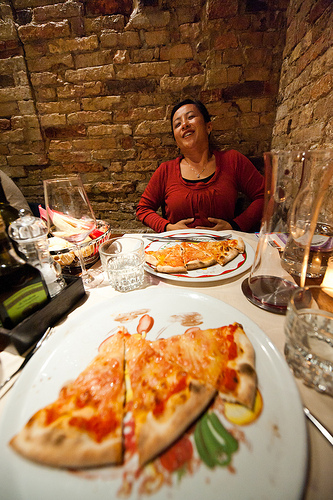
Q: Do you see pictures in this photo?
A: No, there are no pictures.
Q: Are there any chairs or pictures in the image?
A: No, there are no pictures or chairs.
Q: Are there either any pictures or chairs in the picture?
A: No, there are no pictures or chairs.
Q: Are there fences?
A: No, there are no fences.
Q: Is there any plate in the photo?
A: Yes, there is a plate.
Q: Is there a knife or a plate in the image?
A: Yes, there is a plate.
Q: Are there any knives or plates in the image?
A: Yes, there is a plate.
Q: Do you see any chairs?
A: No, there are no chairs.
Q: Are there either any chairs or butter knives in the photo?
A: No, there are no chairs or butter knives.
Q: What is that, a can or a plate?
A: That is a plate.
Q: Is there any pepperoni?
A: Yes, there is pepperoni.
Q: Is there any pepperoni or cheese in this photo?
A: Yes, there is pepperoni.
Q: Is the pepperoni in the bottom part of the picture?
A: Yes, the pepperoni is in the bottom of the image.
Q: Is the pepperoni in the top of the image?
A: No, the pepperoni is in the bottom of the image.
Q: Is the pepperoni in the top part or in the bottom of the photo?
A: The pepperoni is in the bottom of the image.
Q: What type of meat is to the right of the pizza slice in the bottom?
A: The meat is pepperoni.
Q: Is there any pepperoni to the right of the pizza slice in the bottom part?
A: Yes, there is pepperoni to the right of the pizza slice.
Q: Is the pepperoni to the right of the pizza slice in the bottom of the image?
A: Yes, the pepperoni is to the right of the pizza slice.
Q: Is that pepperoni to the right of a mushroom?
A: No, the pepperoni is to the right of the pizza slice.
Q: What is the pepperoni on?
A: The pepperoni is on the plate.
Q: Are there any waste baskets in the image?
A: No, there are no waste baskets.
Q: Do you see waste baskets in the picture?
A: No, there are no waste baskets.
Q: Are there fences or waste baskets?
A: No, there are no waste baskets or fences.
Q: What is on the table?
A: The basket is on the table.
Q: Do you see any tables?
A: Yes, there is a table.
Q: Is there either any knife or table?
A: Yes, there is a table.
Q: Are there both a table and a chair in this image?
A: No, there is a table but no chairs.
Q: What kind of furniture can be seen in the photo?
A: The furniture is a table.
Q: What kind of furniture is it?
A: The piece of furniture is a table.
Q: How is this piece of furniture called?
A: That is a table.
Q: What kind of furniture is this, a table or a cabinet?
A: That is a table.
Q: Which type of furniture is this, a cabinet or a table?
A: That is a table.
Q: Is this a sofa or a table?
A: This is a table.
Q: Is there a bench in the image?
A: No, there are no benches.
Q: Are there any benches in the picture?
A: No, there are no benches.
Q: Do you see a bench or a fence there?
A: No, there are no benches or fences.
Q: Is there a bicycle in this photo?
A: No, there are no bicycles.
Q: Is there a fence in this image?
A: No, there are no fences.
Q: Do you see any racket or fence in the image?
A: No, there are no fences or rackets.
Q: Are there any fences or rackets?
A: No, there are no fences or rackets.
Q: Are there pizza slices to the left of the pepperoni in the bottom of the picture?
A: Yes, there is a pizza slice to the left of the pepperoni.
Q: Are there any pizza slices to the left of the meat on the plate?
A: Yes, there is a pizza slice to the left of the pepperoni.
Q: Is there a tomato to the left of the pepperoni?
A: No, there is a pizza slice to the left of the pepperoni.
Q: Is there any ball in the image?
A: No, there are no balls.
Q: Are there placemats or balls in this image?
A: No, there are no balls or placemats.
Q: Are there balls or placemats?
A: No, there are no balls or placemats.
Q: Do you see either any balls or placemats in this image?
A: No, there are no balls or placemats.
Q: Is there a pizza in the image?
A: Yes, there is a pizza.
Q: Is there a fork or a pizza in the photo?
A: Yes, there is a pizza.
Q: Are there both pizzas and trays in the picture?
A: No, there is a pizza but no trays.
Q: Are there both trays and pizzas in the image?
A: No, there is a pizza but no trays.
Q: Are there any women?
A: Yes, there is a woman.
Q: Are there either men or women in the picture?
A: Yes, there is a woman.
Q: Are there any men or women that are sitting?
A: Yes, the woman is sitting.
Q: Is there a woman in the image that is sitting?
A: Yes, there is a woman that is sitting.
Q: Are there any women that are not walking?
A: Yes, there is a woman that is sitting.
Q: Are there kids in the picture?
A: No, there are no kids.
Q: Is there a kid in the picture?
A: No, there are no children.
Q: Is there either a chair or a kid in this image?
A: No, there are no children or chairs.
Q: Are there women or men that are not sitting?
A: No, there is a woman but she is sitting.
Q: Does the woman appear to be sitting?
A: Yes, the woman is sitting.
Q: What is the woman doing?
A: The woman is sitting.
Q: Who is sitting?
A: The woman is sitting.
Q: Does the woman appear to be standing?
A: No, the woman is sitting.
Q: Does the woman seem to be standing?
A: No, the woman is sitting.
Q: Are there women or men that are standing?
A: No, there is a woman but she is sitting.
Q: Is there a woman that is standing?
A: No, there is a woman but she is sitting.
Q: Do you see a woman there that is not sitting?
A: No, there is a woman but she is sitting.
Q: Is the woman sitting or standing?
A: The woman is sitting.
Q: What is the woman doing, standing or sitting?
A: The woman is sitting.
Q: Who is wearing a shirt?
A: The woman is wearing a shirt.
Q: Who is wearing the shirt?
A: The woman is wearing a shirt.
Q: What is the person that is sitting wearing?
A: The woman is wearing a shirt.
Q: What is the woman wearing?
A: The woman is wearing a shirt.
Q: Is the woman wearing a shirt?
A: Yes, the woman is wearing a shirt.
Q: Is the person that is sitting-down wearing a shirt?
A: Yes, the woman is wearing a shirt.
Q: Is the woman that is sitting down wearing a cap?
A: No, the woman is wearing a shirt.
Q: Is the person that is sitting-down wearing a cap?
A: No, the woman is wearing a shirt.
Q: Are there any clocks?
A: No, there are no clocks.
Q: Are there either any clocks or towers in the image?
A: No, there are no clocks or towers.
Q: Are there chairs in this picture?
A: No, there are no chairs.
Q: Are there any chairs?
A: No, there are no chairs.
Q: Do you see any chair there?
A: No, there are no chairs.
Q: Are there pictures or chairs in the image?
A: No, there are no chairs or pictures.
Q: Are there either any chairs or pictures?
A: No, there are no chairs or pictures.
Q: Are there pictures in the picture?
A: No, there are no pictures.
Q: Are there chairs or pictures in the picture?
A: No, there are no pictures or chairs.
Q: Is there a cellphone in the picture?
A: No, there are no cell phones.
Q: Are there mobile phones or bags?
A: No, there are no mobile phones or bags.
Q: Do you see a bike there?
A: No, there are no bikes.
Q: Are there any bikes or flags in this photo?
A: No, there are no bikes or flags.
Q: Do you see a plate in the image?
A: Yes, there is a plate.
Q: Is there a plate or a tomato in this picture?
A: Yes, there is a plate.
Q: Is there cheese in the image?
A: Yes, there is cheese.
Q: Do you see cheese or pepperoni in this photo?
A: Yes, there is cheese.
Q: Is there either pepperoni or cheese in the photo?
A: Yes, there is cheese.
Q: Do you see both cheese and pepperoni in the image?
A: Yes, there are both cheese and pepperoni.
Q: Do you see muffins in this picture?
A: No, there are no muffins.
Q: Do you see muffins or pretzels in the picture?
A: No, there are no muffins or pretzels.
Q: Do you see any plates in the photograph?
A: Yes, there is a plate.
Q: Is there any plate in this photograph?
A: Yes, there is a plate.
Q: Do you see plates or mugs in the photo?
A: Yes, there is a plate.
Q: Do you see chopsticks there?
A: No, there are no chopsticks.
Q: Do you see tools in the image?
A: No, there are no tools.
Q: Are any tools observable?
A: No, there are no tools.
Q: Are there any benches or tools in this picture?
A: No, there are no tools or benches.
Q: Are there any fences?
A: No, there are no fences.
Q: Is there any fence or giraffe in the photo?
A: No, there are no fences or giraffes.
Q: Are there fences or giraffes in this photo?
A: No, there are no fences or giraffes.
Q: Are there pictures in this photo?
A: No, there are no pictures.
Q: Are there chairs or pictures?
A: No, there are no pictures or chairs.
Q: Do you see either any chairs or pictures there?
A: No, there are no pictures or chairs.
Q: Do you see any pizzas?
A: Yes, there is a pizza.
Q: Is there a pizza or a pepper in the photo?
A: Yes, there is a pizza.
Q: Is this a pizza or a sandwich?
A: This is a pizza.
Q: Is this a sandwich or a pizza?
A: This is a pizza.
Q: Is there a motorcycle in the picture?
A: No, there are no motorcycles.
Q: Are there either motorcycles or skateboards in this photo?
A: No, there are no motorcycles or skateboards.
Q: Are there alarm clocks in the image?
A: No, there are no alarm clocks.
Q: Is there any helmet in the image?
A: No, there are no helmets.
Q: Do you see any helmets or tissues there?
A: No, there are no helmets or tissues.